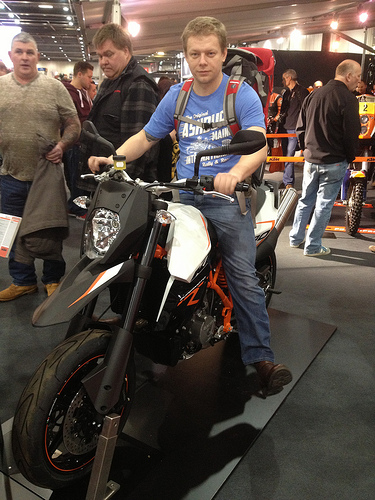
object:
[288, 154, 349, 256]
jeans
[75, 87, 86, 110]
string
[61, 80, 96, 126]
hoodie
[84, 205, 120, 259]
light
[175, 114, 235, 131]
grey strap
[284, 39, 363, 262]
man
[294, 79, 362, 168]
coat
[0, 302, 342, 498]
stand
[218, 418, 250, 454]
shadow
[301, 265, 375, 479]
carpet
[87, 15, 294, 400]
man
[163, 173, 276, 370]
jeans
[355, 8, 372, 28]
lights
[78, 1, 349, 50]
ceiling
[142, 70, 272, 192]
shirt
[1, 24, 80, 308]
person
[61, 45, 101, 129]
person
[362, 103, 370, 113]
2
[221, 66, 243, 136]
straps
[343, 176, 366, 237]
tire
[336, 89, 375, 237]
bike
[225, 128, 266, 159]
mirror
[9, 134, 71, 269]
coat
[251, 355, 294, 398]
boot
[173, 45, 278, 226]
backpack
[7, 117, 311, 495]
motorcycle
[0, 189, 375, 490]
floor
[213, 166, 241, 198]
hand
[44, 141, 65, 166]
hand